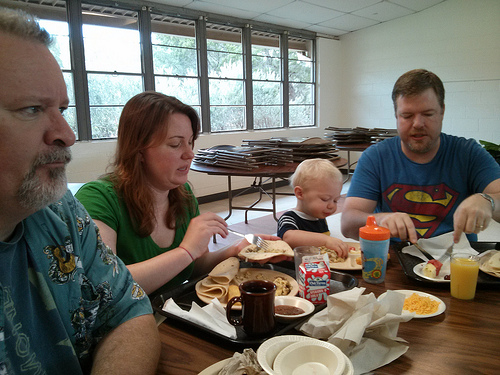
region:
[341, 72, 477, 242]
Man wearing a superman shirt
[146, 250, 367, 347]
Black rectangular tray with plates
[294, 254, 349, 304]
Red and white milk container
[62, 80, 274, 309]
Woman wearing green shirt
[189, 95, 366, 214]
Grey chairs on table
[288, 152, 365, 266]
Boy with black and white shirt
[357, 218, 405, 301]
Orange and blue sippy cup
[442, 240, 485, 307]
Clear cup with orange juice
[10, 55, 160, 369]
Man wearing a blue shirt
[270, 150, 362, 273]
Boy is picking food up from his plate with his hand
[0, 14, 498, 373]
a family eating together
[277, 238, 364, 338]
a red milk carton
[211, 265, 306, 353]
a brown coffee mug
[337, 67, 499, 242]
a man wearing a superman shirt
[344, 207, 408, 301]
a sippy cup with an orange lid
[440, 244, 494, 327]
a glass of orange juice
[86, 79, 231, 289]
a woman in a green shirt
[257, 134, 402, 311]
a young child eating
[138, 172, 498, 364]
breakfast food on the table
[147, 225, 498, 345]
two black plastic trays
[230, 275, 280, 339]
dark brown coffe mug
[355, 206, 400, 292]
blue sippy cup with orange lid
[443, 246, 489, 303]
clear plastic cup with orange juice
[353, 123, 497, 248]
man T hsirt with superman logo on it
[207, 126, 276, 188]
chiars stacked up on table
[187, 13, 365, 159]
multi pane windows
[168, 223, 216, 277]
ladies red braclet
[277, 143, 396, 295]
little boy eating with fingers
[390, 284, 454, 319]
macaroni and cheese on white plate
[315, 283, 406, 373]
napkins bunched oup on table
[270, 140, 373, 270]
a baby eating with his hands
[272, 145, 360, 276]
the baby is blond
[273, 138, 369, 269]
the baby has his mouth full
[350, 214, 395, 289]
a baby cup that is orange and blue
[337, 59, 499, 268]
a man wears a blue shirt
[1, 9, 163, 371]
man has bear and gray hair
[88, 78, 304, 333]
a woman holding a fork with her left hand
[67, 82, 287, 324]
woman wears a green shirt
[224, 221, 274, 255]
fork is silver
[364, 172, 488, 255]
superman logo on man's shirt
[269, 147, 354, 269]
little boy is eating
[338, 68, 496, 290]
man is cutting food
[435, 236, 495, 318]
glass of orange juice on table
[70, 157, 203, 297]
woman's shirt is green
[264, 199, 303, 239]
boy's shirt has stripes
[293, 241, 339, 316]
red carton on table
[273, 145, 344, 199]
boy's hair is blonde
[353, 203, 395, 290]
sippy cup has orange top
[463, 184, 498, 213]
man is wearing watch